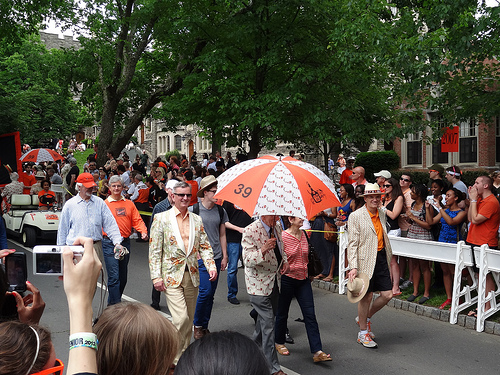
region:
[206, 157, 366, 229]
The man is holding a umbrella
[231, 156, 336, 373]
A man and lady is walking under an umbrella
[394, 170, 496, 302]
People are standing behind the barricade.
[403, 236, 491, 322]
The barricade is white.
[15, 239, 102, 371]
A person is taking a picture with a cell phone.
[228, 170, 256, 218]
The umbrella has the number 39 written on it.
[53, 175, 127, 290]
A man is wearing an orange cap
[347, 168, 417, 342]
a man has a hat in his hand and on his head.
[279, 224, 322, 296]
The woman is carrying a black purse.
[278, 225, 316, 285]
The shirt is red and white with stripes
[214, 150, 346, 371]
man is carrying umbrella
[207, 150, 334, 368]
woman next to the man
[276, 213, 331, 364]
woman is under the umbrella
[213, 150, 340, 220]
the umbrella is red and white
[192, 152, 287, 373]
the man's jacket matches the umbrella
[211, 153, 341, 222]
the umbrella has solid panels and patterned panels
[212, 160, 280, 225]
The number 39 on a red panel of the umbrella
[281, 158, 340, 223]
A logo is on the red panel of an umbrella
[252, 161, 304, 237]
A red pattern on a white background i on the umbrella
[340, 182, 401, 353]
the man is walking down the street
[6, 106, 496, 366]
A large parade.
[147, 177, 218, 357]
The man is wearing a blazer with a design on it.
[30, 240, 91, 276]
A person holding a digital camera.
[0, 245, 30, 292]
A black smartphone.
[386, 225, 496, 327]
Barriers to hold back the crowd.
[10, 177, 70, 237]
A woman driving a white golf cart.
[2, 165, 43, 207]
Two people being carried by the golf cart.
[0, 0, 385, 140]
Large trees providing shade.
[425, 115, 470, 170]
A sign with 2007 written on it.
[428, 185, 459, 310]
A woman in a blue shirt.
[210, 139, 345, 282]
orange and white umbrella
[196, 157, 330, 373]
man walking under umbrella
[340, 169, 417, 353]
man wearing a hat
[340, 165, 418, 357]
man holding hat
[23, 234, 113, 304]
silver camera to take pictures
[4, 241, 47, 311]
lady holding black cellphone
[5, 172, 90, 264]
white golf cart on road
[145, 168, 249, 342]
man wearing floral jacket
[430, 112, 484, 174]
orange poster sign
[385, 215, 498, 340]
white stand fence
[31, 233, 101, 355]
Hand holds camera for pics.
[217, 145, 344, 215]
Umbrella has number 39 on it.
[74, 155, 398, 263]
Color orange is theme.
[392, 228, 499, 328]
Barricades keep crowd back.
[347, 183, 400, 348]
Hat on his head and one in hand.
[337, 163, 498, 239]
Crowd watches parade.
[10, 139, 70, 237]
Vehicle carries parade members.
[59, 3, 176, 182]
Large green tree background.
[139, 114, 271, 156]
Tan building with windows.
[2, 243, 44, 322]
Cellphone takes pictures.